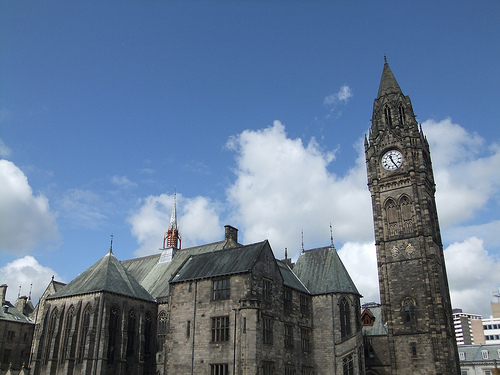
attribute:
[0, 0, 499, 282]
sky — blue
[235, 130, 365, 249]
clouds patch — white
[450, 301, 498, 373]
building — white, partially blocked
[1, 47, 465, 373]
building — old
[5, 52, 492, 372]
town — ancient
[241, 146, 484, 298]
sky — blue, cloudy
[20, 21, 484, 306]
sky — blue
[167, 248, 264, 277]
roof — dark black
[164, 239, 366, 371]
building — old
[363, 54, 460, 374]
tower — tall, on the right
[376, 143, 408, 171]
clock — white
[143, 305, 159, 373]
window — long, narrow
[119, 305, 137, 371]
window — long, narrow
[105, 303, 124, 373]
window — long, narrow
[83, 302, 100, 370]
window — long, narrow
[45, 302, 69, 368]
window — long, narrow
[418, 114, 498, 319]
cloud — white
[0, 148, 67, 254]
cloud — white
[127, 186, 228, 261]
cloud — white